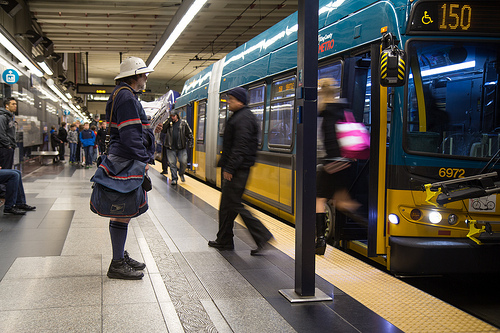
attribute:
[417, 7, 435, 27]
handicap sign — train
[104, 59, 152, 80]
hat — canvas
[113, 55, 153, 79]
hard hat — hard 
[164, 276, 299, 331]
floor — dark color, platform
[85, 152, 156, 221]
bag — postal 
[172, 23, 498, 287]
train — blue , yellow 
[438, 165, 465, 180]
number — 6972 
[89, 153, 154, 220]
bag — large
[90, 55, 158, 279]
man — old 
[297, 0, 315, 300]
pillar — black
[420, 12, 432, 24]
handicapped symbol — handicapped 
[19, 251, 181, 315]
floor — tile 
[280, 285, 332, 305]
base — metallic, metal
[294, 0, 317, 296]
beam — iron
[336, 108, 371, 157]
bag — yellow and pink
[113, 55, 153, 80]
hat — wide brimmed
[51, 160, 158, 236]
satchel — hanging on side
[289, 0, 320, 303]
beam — iron, grey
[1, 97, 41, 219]
man — young 